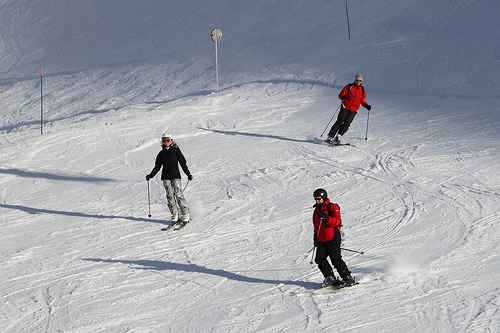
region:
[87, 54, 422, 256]
these are skiers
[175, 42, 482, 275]
there are three skiers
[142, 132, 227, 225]
the jacket is black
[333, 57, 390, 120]
the jacket is red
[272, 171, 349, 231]
the helmet is black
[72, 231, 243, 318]
there are tracks in the snow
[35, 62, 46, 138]
Pole in the snow.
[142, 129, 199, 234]
Woman in a black coat skiing.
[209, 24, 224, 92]
A round top sign in the snow.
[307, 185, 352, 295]
A man in a red jacket skiing.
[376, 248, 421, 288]
Kicked up snow.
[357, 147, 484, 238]
Ski tracks in the snow.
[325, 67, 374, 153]
A man in red and black skiing.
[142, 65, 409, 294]
People on a ski slope.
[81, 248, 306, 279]
A shadow on the snow.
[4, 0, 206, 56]
Snow on a hillside.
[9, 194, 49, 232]
white snow on hill side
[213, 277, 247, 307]
white snow on hill side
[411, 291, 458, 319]
white snow on hill side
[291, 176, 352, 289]
skier in red jacket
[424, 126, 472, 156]
white snow on hill side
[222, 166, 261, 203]
white snow on hill side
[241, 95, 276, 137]
white snow on hill side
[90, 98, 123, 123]
white snow on hill side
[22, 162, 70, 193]
white snow on hill side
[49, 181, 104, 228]
white snow on hill side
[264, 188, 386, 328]
a person skiing on the snow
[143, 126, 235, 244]
a perosn sking on the snow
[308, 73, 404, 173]
a person sking on the snow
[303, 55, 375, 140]
a person wearing a jacket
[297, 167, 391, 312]
a person wearing a jacket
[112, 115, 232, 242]
a person wearing jacket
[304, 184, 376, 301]
a person wearing a red jacket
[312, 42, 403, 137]
a person wearing red jacket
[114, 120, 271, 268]
a person wearing a black jacket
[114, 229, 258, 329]
snow covering the ground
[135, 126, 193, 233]
skier in white snow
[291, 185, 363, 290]
skier in white snow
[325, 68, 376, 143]
skier in white snow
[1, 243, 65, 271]
white snow on hill side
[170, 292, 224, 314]
white snow on hill side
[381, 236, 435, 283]
white snow on hill side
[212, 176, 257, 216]
white snow on hill side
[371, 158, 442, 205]
white snow on hill side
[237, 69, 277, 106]
white snow on hill side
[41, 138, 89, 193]
white snow on hill side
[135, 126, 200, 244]
skier in white snow on hill side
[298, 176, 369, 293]
skier in white snow on hill side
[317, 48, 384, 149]
skier in white snow on hill side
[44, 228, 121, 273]
white snow on hill side